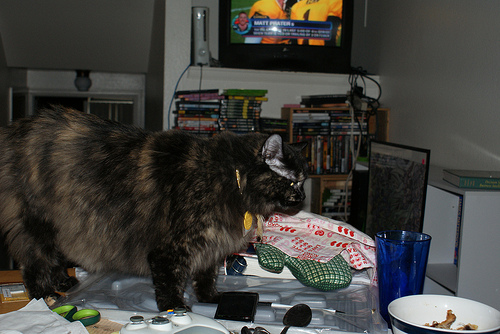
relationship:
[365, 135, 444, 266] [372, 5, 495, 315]
poster against wall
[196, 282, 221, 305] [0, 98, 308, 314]
paw of cat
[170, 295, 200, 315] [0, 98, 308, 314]
paw of cat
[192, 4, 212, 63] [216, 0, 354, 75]
game console next to tv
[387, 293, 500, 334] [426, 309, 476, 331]
bowl with food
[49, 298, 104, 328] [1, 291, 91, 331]
scissors beneath paper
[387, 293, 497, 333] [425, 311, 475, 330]
bowl of food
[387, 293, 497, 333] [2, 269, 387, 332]
bowl on table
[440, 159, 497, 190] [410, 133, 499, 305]
book on shelf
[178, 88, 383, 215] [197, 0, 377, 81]
video games are under tv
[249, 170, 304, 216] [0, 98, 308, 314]
face of cat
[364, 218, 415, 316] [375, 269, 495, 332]
glass beside bowl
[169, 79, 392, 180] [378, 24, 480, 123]
dvds near wall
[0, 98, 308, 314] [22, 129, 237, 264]
cat has fur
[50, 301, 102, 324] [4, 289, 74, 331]
scissors under paper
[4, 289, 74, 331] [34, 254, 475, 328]
paper on table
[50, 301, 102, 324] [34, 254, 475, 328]
scissors on table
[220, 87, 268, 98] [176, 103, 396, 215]
dvds on shelf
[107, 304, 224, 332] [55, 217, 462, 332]
game controller on table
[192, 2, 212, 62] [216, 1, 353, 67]
game console by tv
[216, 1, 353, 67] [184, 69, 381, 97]
tv on shelf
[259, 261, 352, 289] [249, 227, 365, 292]
section of oven mitt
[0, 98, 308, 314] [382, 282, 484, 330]
cat looking towards bowl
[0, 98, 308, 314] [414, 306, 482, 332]
cat looking towards food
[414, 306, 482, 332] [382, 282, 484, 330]
food in bowl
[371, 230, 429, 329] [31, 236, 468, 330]
glass on table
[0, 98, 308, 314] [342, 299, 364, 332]
cat stands on table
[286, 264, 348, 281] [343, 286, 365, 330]
mitt on table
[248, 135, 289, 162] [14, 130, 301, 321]
ear belongs to cat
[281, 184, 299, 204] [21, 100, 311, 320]
nose belongs to cat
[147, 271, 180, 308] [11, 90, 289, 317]
leg belongs to cat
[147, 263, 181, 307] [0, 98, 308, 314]
leg belongs to cat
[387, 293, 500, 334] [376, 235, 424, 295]
bowl sit next glass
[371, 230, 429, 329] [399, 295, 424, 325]
glass sit next bowl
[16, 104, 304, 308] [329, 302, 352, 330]
cat on table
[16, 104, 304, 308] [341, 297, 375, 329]
cat over table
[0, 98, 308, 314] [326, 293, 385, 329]
cat on table